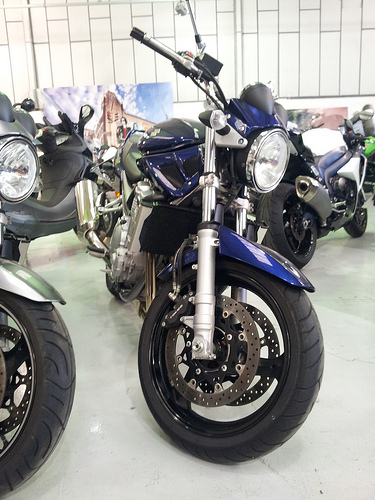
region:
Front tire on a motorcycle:
[149, 268, 328, 475]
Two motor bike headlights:
[0, 63, 297, 245]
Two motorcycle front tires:
[3, 281, 300, 466]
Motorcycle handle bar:
[104, 10, 245, 98]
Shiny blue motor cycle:
[110, 36, 315, 412]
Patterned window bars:
[240, 12, 366, 82]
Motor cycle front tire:
[263, 395, 372, 485]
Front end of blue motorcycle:
[237, 111, 335, 456]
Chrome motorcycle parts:
[176, 118, 250, 401]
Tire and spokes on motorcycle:
[156, 274, 296, 449]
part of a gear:
[148, 40, 207, 91]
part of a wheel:
[200, 422, 256, 472]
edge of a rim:
[196, 390, 240, 441]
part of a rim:
[192, 370, 237, 441]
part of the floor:
[108, 422, 156, 471]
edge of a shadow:
[124, 386, 154, 437]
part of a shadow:
[128, 382, 157, 435]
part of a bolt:
[186, 340, 221, 359]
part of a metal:
[191, 298, 212, 325]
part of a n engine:
[106, 271, 138, 314]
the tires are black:
[0, 238, 326, 497]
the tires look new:
[0, 257, 326, 498]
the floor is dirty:
[0, 195, 374, 498]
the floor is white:
[1, 189, 373, 498]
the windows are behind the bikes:
[2, 2, 373, 122]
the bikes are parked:
[0, 1, 355, 499]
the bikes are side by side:
[0, 54, 330, 498]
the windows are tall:
[0, 1, 373, 107]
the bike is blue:
[97, 92, 340, 474]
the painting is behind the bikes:
[31, 83, 172, 160]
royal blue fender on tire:
[214, 221, 322, 298]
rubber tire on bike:
[280, 369, 322, 430]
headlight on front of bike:
[242, 126, 293, 195]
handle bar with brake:
[127, 18, 202, 79]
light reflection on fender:
[10, 262, 70, 304]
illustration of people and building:
[90, 87, 165, 140]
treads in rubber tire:
[45, 345, 72, 405]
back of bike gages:
[239, 77, 293, 122]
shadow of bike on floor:
[111, 302, 145, 425]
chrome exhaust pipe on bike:
[66, 174, 107, 245]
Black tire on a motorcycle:
[136, 243, 333, 472]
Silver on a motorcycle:
[150, 285, 273, 388]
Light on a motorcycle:
[229, 115, 283, 210]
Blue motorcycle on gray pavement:
[102, 121, 304, 277]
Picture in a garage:
[41, 78, 179, 137]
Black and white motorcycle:
[253, 115, 374, 246]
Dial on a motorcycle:
[224, 69, 289, 118]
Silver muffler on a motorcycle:
[294, 165, 366, 232]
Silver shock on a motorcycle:
[185, 226, 230, 386]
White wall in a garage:
[75, 43, 323, 123]